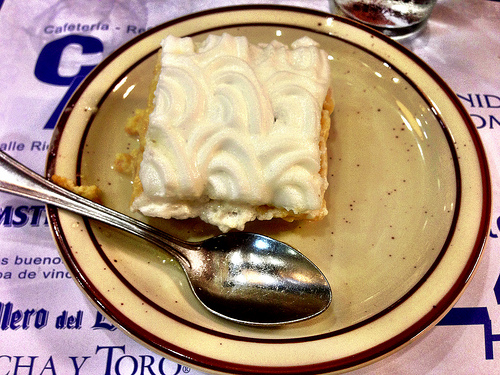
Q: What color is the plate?
A: Brown.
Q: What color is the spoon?
A: Silver.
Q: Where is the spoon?
A: On the plate.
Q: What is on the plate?
A: Dessert.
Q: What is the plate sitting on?
A: The table.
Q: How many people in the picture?
A: None.